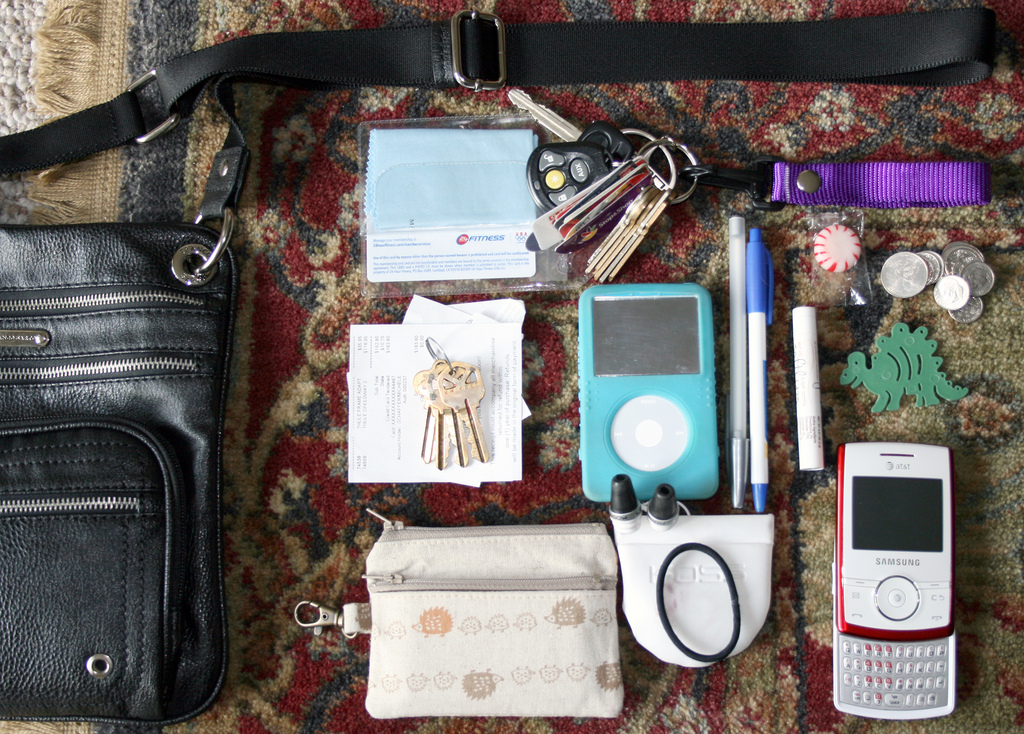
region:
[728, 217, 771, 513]
Blue and white ink pens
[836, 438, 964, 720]
A samsung blackberry phone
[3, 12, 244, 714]
A black leather fannypack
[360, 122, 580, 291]
Special cloth for cleaning electronics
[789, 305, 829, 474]
White tube of lip gloss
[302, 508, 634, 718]
White wallet with hedgehog design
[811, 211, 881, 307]
Single peppermint candy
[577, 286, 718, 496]
the ipod is blue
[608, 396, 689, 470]
the circle is white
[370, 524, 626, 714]
the wallet is white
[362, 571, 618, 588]
the zipper is gray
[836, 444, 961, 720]
red and white phone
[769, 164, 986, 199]
the thing is purple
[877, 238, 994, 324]
a pile of coins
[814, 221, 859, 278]
red and white mint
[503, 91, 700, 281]
a set of keys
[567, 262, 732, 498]
ipod with blue cover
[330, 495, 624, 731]
white coin purse with porcupines on it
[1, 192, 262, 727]
body of the black crossbody bag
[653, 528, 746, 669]
black hair tie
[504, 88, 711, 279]
keys to this girls stuff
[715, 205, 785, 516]
two pens lying next to each other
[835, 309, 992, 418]
green dinosaur stencil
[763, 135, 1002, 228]
purple wrist strap for the keys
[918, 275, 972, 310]
a round silver metal coin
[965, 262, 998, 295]
a round silver metal coin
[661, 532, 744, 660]
a black hair tie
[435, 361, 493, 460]
a gold key on a keyring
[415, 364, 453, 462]
a gold key on a keyring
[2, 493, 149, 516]
the closed zipper of a purse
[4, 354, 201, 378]
the closed zipper of a purse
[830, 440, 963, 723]
a candy bar style cell phone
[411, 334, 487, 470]
a set of car keys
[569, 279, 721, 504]
an iPod Classic with blue case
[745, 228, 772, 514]
a blue ballpoint pen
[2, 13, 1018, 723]
a black leather purse with strap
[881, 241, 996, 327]
a collection of silver coins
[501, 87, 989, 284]
a key ring with keys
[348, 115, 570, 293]
a plastic lanyard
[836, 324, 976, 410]
a green dinosaur toy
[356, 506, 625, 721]
a small tan pouch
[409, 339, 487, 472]
a set of keys on some papers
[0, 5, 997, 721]
a black leather bag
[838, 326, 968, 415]
a green dinosaur shaped air freshener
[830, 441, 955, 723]
a white and red cellphone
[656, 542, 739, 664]
a small black rubber band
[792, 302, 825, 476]
a stick of white chalk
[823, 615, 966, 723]
Buttons on a blackberry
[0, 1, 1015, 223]
Black strap of a bag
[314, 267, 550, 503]
Keys on white paper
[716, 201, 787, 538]
A blue and white pen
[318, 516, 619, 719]
An item on a rug.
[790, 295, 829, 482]
An item on a rug.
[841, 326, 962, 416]
An item on a rug.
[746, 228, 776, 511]
An item on a rug.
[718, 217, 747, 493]
An item on a rug.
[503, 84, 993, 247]
An item on a rug.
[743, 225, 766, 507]
An item on the rug.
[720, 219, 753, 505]
An item on the rug.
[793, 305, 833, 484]
An item on the rug.